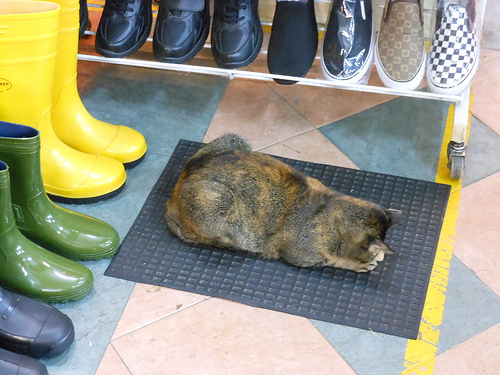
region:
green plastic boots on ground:
[0, 117, 134, 306]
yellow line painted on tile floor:
[395, 339, 447, 373]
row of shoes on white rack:
[82, 0, 472, 107]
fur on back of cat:
[227, 175, 277, 213]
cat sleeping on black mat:
[166, 128, 401, 301]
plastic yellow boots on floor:
[0, 3, 150, 193]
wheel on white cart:
[442, 135, 472, 182]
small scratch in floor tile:
[274, 137, 316, 154]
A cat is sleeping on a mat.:
[100, 130, 454, 345]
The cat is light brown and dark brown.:
[157, 131, 402, 277]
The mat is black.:
[98, 136, 450, 341]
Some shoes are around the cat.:
[0, 0, 491, 373]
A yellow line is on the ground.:
[399, 75, 473, 374]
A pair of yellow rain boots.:
[3, 0, 148, 211]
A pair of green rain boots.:
[0, 121, 117, 302]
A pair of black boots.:
[0, 286, 74, 372]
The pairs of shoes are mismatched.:
[267, 0, 482, 102]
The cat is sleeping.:
[161, 125, 406, 280]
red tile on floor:
[116, 277, 201, 322]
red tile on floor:
[98, 345, 129, 373]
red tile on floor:
[435, 323, 499, 369]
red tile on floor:
[444, 170, 499, 292]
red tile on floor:
[251, 130, 357, 174]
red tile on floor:
[203, 70, 312, 157]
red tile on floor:
[259, 68, 396, 127]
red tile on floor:
[463, 58, 498, 140]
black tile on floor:
[321, 91, 496, 206]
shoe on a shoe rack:
[425, 1, 482, 90]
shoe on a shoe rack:
[376, 3, 426, 88]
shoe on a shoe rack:
[318, 1, 374, 88]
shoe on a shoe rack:
[266, 6, 319, 87]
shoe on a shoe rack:
[210, 2, 263, 63]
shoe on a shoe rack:
[153, 3, 209, 63]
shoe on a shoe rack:
[92, 1, 154, 54]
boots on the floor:
[1, 38, 145, 192]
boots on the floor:
[1, 120, 122, 305]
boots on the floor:
[1, 286, 77, 373]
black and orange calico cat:
[159, 131, 402, 268]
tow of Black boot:
[1, 286, 76, 356]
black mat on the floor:
[103, 137, 451, 339]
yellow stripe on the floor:
[402, 80, 470, 370]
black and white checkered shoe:
[428, 0, 483, 92]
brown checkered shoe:
[373, 1, 425, 88]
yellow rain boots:
[1, 2, 148, 205]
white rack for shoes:
[75, 4, 473, 180]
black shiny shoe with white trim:
[324, 7, 370, 85]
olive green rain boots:
[1, 121, 119, 306]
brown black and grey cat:
[163, 132, 407, 276]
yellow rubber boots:
[0, 0, 149, 204]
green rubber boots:
[0, 118, 123, 305]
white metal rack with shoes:
[79, 0, 487, 103]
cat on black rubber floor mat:
[98, 134, 453, 339]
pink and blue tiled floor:
[43, 28, 496, 374]